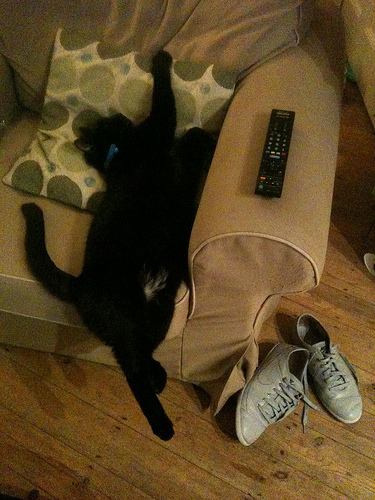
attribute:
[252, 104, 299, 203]
remote — black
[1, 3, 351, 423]
couch — tan, brown, velvet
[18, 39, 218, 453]
cat — black, stretched out, sleeping, long, laying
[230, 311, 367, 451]
shoes — white, grey, gray, pair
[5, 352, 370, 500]
floor — brown, wooden, yellow, hardwood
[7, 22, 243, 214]
pillow — white, green, blue, square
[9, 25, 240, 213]
dots — green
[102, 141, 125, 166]
collar — blue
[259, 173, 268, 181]
button — orange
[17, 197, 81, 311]
tail — black, long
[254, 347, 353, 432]
shoelaces — white, gray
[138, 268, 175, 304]
hair — white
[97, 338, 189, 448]
legs — hanging